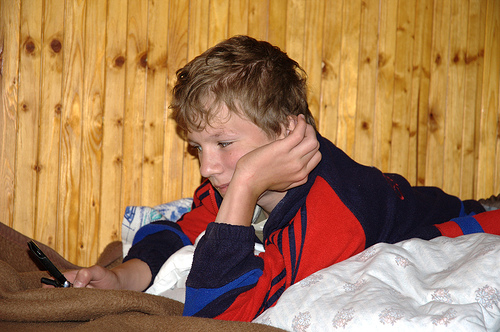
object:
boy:
[41, 35, 500, 322]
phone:
[26, 240, 74, 287]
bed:
[251, 232, 499, 331]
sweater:
[122, 130, 500, 322]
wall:
[0, 0, 500, 268]